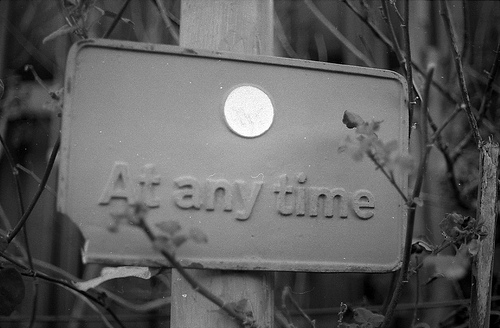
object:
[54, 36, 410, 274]
sign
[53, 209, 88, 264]
corner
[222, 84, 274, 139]
circle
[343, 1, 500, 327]
branches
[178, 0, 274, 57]
pole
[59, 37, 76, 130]
edges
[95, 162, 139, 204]
letter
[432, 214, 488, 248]
leaves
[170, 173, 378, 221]
writing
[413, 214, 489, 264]
flower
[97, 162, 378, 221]
at any time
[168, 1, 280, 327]
post